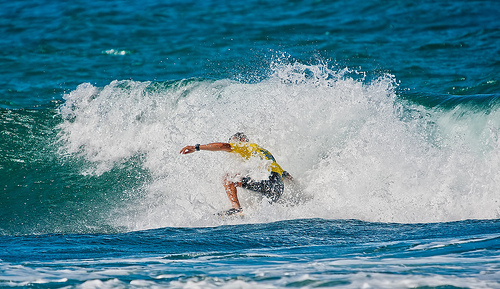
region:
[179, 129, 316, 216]
Athletic person surfing in ocean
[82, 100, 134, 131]
Churning white ocean surf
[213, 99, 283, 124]
Churning white ocean surf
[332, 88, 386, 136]
Churning white ocean surf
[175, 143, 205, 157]
Hand of ocean surfer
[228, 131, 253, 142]
Head of ocean surfer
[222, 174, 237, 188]
Knee of ocean surfer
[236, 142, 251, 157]
shoulder of ocean surfer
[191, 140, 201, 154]
Watch of ocean surfer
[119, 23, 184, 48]
refreshing blue ocean water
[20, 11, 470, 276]
rider plowing through the waves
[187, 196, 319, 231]
board hidden under waves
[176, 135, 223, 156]
man's arm extended for balance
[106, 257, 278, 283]
foaming water near the shore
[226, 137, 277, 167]
surfer's yellow top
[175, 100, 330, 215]
white water sprays around the rider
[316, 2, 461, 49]
still blue water offshore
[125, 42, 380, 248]
surfer riding low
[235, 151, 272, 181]
water splashing back onto the man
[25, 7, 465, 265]
a man surfing in the ocean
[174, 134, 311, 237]
surfer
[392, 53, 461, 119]
dark blue water and white waves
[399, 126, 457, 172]
dark blue water and white waves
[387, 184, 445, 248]
dark blue water and white waves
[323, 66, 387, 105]
dark blue water and white waves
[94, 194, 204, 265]
dark blue water and white waves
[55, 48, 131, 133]
dark blue water and white waves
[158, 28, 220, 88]
dark blue water and white waves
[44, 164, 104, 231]
dark blue water and white waves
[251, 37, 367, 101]
dark blue water and white waves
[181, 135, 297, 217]
a man surfing in the ocean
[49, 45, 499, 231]
white foam on a wave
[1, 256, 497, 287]
a gentle wave on the ocean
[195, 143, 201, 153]
man wearing a black watch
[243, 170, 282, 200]
man wearing black shots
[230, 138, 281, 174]
man wearing a yellow shirt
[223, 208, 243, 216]
man wearing black shoes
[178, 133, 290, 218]
man standing on a surfboard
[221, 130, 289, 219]
man wearing wet clothes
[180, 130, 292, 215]
man about to disappear behind a wave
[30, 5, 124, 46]
white clouds in blue sky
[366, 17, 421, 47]
white clouds in blue sky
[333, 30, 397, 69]
white clouds in blue sky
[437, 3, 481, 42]
white clouds in blue sky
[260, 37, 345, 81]
white clouds in blue sky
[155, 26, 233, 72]
white clouds in blue sky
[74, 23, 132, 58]
white clouds in blue sky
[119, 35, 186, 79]
white clouds in blue sky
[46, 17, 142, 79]
white clouds in blue sky